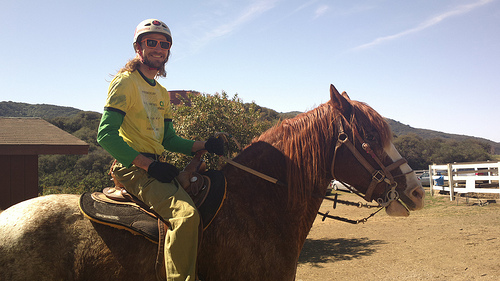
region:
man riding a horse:
[2, 15, 432, 276]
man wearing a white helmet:
[128, 18, 173, 80]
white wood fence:
[420, 155, 498, 200]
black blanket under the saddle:
[77, 146, 234, 259]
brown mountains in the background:
[3, 84, 493, 180]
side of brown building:
[2, 108, 100, 210]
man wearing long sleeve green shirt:
[87, 19, 224, 181]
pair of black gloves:
[143, 133, 229, 188]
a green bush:
[159, 83, 270, 174]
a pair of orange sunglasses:
[137, 33, 174, 55]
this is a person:
[104, 15, 209, 280]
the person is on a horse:
[0, 81, 451, 276]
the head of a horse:
[314, 84, 434, 238]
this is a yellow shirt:
[93, 63, 178, 174]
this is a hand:
[92, 60, 178, 212]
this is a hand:
[153, 78, 245, 182]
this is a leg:
[129, 170, 192, 280]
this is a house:
[0, 110, 87, 210]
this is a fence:
[424, 154, 498, 225]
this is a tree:
[140, 81, 292, 246]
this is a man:
[99, 15, 214, 276]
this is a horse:
[7, 83, 441, 278]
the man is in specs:
[139, 33, 178, 65]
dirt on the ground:
[337, 239, 395, 276]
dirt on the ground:
[434, 223, 470, 266]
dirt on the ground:
[384, 238, 416, 269]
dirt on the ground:
[477, 210, 498, 262]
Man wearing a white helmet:
[126, 17, 187, 76]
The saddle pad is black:
[76, 169, 231, 243]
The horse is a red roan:
[0, 80, 434, 273]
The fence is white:
[425, 158, 494, 198]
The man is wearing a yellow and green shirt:
[103, 23, 212, 180]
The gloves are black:
[141, 134, 223, 184]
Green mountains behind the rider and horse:
[12, 84, 485, 181]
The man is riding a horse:
[16, 10, 426, 280]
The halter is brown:
[325, 89, 407, 200]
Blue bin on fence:
[430, 171, 449, 192]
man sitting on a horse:
[95, 18, 234, 279]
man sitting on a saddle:
[92, 184, 162, 216]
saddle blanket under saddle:
[79, 184, 157, 241]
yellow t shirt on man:
[103, 65, 174, 157]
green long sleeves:
[96, 108, 139, 165]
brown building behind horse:
[2, 116, 87, 206]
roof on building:
[1, 115, 90, 155]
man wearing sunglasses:
[140, 38, 172, 52]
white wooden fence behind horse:
[426, 156, 497, 204]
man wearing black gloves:
[148, 160, 179, 182]